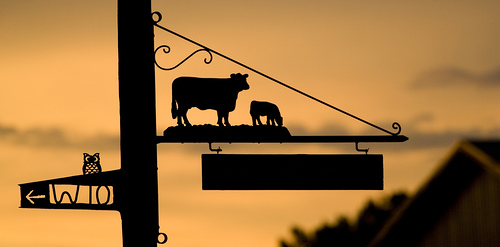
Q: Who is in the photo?
A: No one.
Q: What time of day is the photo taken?
A: In the evening.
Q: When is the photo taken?
A: During dusk.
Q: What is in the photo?
A: Images of animals.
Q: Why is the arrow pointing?
A: To show the direction.